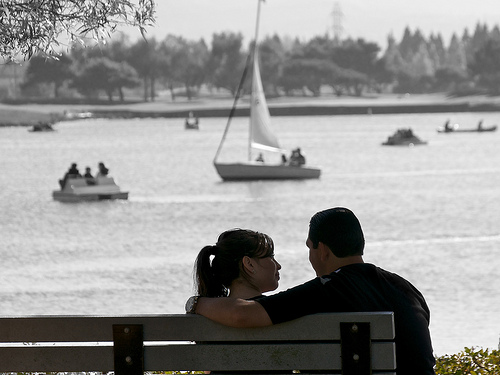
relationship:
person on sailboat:
[256, 151, 265, 163] [211, 1, 320, 182]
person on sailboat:
[280, 151, 288, 166] [211, 1, 320, 182]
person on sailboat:
[291, 149, 298, 166] [211, 1, 320, 182]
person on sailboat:
[298, 147, 308, 165] [211, 1, 320, 182]